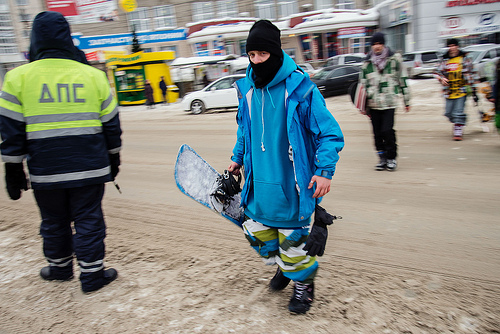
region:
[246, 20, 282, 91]
a black knitted face mask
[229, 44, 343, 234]
a big blue winter coat with a hood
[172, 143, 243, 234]
a blue and white snow board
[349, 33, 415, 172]
a person dressed for cold weather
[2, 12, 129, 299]
a person dressed for cold weather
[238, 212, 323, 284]
green, white and blue ski pants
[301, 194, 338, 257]
black winter gloves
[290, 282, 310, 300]
white shoelaces in a black shoe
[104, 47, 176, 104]
a little yellow and green building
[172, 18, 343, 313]
A person dressed in snowboarding attire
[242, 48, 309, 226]
A sky blue hooded sweatshirt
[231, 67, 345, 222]
A sky blue winter jacket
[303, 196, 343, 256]
A winter black glove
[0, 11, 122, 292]
A person dressed in dark winter clothes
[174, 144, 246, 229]
A light blue snowboard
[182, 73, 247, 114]
A white car going down the street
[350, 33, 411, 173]
A snowboarder wearing black pants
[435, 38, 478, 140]
A person crossing the street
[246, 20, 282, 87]
A black ski mask being worn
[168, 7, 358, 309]
man carrying a snowboard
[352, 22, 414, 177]
man wearing green and white jacket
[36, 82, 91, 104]
gray lettering on yellow background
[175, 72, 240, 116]
white car driving down the street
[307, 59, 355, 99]
black car driving down the street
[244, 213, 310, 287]
green, blue, and white pants of the snowboarder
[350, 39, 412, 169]
snowboarder wearing black pants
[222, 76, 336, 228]
blue hooded sweatshirt and jacket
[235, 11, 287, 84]
black knit cap that covers the face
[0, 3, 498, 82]
row of buildings along the street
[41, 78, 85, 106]
words on the back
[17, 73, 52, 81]
yellow on the jacket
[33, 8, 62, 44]
man wearing a hat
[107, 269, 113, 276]
man has on black shoes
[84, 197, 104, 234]
man has on black pants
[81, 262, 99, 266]
man has a grey stripe on the leg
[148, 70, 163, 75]
yellow on the building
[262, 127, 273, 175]
man has on a blue sweater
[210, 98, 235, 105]
white car on the street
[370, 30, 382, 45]
man wearing a hat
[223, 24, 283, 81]
The man is wearing a ski mask.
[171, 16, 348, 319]
man in blue jacket holding snowboard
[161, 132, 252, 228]
white and blue colored snowboard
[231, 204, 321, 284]
white, blue, and green colored snowboarding pants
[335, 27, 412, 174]
man in tan and green jacket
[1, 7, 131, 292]
man wearing a light green and blue jacket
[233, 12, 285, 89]
black colored ski hood of man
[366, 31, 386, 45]
black colored hat of man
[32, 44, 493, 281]
street covered in slushy snow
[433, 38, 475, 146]
man wearing a yellow, black and red colored shirt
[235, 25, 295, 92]
a man wearing a ski mask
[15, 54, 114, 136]
a neon green jacket with the letters ANC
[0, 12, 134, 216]
a man wearing a green and black jacket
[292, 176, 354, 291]
a glove hanging from the person's jacket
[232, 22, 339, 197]
a male wearing a blue jacket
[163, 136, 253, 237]
a blue and white surfboard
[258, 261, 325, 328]
a pair of black rubber shoes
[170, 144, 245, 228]
A blue snowboard with snow on top.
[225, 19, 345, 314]
Man in long blue sweatshirt carrying a snowboard.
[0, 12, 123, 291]
Man turned around in black, silver and yellow clothes.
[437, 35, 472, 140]
Black haired man in yellow shirt.